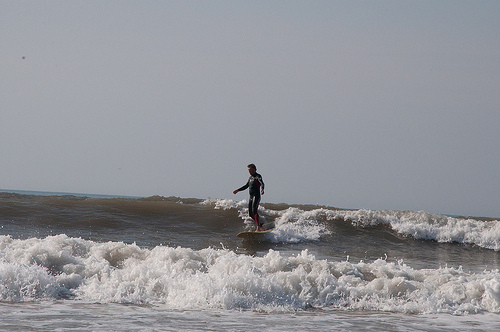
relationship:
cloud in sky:
[0, 0, 500, 220] [4, 1, 496, 220]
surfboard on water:
[229, 224, 280, 243] [0, 188, 500, 332]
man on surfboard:
[232, 163, 264, 233] [232, 224, 278, 239]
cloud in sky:
[7, 10, 494, 216] [4, 1, 496, 220]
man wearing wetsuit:
[232, 163, 264, 233] [235, 173, 263, 225]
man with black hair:
[232, 163, 264, 233] [246, 162, 256, 173]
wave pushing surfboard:
[0, 197, 500, 329] [241, 227, 271, 235]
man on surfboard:
[232, 163, 264, 233] [237, 228, 274, 242]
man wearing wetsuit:
[232, 163, 264, 233] [236, 172, 263, 220]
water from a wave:
[339, 162, 486, 329] [334, 194, 468, 304]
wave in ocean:
[0, 233, 500, 318] [14, 197, 202, 246]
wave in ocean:
[0, 233, 500, 318] [39, 218, 171, 293]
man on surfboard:
[232, 163, 264, 233] [238, 227, 278, 238]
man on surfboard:
[232, 163, 264, 233] [235, 227, 292, 249]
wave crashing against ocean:
[0, 233, 500, 318] [9, 180, 496, 323]